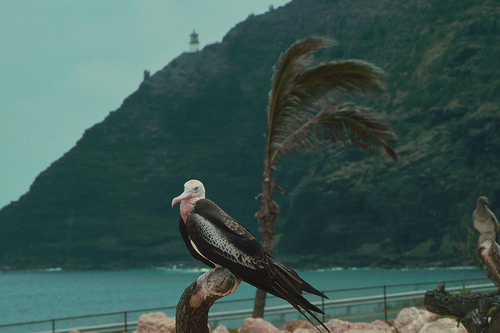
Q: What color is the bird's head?
A: White.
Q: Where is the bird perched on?
A: On the tree.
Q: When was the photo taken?
A: Daytime.